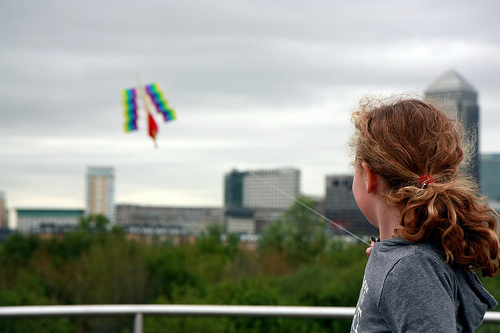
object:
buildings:
[83, 162, 120, 234]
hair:
[349, 92, 499, 275]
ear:
[358, 160, 378, 195]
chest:
[352, 244, 399, 330]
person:
[349, 94, 500, 332]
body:
[344, 234, 499, 332]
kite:
[121, 80, 180, 152]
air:
[31, 37, 106, 129]